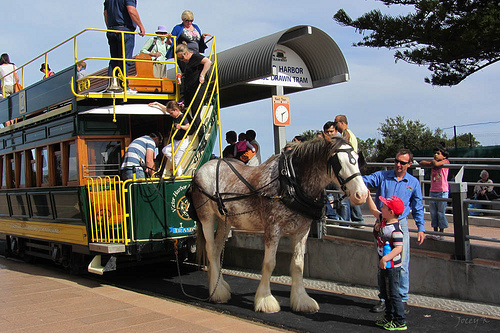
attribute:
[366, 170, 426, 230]
shirt — blue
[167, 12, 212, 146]
people — descending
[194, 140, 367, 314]
horse — white, brown, cream, small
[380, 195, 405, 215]
cap — red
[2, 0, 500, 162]
sky — blue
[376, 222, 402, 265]
shirt — striped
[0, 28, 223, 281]
carriage — green, yellow, double deck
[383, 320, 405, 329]
sneakers — green, black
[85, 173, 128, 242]
gate — yellow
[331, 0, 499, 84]
branches — overhanging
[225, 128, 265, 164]
people — waiting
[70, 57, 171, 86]
bench — brown